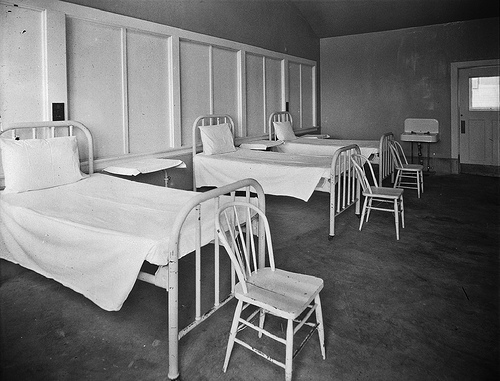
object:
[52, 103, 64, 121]
outlet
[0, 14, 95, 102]
wall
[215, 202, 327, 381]
chair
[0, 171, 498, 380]
floor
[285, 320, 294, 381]
leg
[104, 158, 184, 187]
table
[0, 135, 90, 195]
pillow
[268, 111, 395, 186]
bed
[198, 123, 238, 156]
pillow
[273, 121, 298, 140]
pillow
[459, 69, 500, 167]
white door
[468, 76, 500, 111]
window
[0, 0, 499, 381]
photo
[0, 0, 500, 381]
room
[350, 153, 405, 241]
chair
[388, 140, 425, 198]
chair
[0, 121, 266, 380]
bed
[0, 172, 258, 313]
linens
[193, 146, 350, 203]
linens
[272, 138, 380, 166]
linens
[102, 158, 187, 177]
cloth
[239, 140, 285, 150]
cloth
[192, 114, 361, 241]
bed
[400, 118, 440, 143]
sink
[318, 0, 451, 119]
wall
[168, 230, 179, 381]
frame